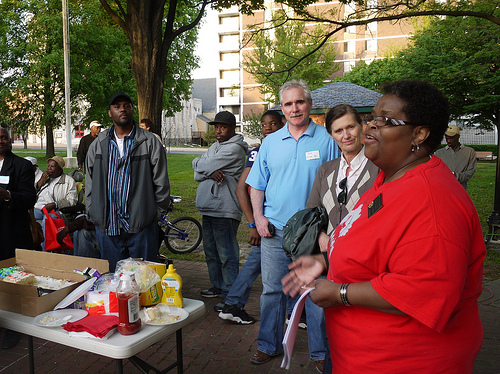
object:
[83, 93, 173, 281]
man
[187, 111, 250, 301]
man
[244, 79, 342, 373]
man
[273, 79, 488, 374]
woman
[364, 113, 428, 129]
glasses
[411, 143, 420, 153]
earring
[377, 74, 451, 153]
hair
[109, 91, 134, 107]
cap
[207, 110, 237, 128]
cap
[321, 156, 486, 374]
shirt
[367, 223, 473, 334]
sleeve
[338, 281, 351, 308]
bracelet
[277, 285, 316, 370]
paper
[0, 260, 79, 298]
cake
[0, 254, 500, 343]
table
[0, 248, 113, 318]
box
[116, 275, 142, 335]
ketchup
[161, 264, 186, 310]
mustard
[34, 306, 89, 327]
plate